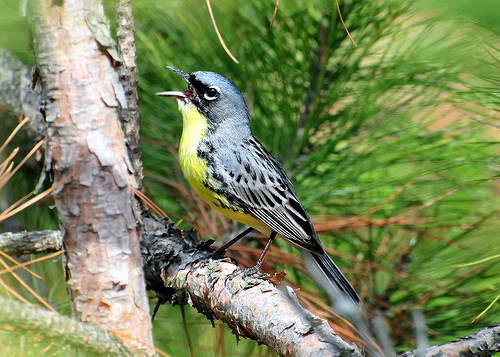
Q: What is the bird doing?
A: Singing.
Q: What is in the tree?
A: A bird.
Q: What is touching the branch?
A: Bird feet.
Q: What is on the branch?
A: A bird.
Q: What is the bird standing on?
A: A branch.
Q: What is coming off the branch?
A: Pieces of bark.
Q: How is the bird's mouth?
A: Open.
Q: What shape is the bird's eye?
A: Round.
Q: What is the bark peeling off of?
A: The branches.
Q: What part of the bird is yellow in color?
A: The underside.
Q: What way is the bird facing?
A: Left.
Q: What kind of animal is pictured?
A: A bird.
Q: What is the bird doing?
A: Standing.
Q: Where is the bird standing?
A: On a branch.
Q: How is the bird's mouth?
A: Open.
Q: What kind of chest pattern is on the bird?
A: A yellow chest.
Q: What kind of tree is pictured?
A: An evergreen.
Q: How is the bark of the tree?
A: Flaky.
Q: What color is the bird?
A: Blue and yellow.